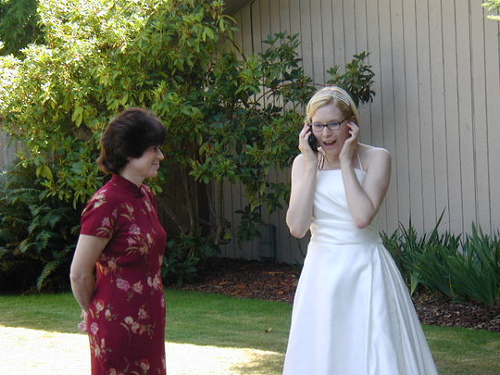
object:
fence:
[162, 4, 498, 261]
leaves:
[241, 264, 263, 280]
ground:
[0, 257, 500, 375]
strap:
[350, 146, 367, 172]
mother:
[69, 111, 170, 374]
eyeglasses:
[309, 117, 350, 133]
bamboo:
[219, 49, 237, 272]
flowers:
[122, 229, 142, 250]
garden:
[409, 228, 499, 299]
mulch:
[213, 258, 285, 297]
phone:
[301, 112, 322, 152]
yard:
[0, 0, 500, 375]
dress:
[279, 168, 440, 375]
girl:
[277, 84, 440, 375]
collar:
[111, 176, 145, 195]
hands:
[74, 308, 93, 333]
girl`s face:
[306, 100, 353, 154]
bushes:
[1, 157, 99, 312]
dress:
[77, 173, 171, 375]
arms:
[68, 200, 116, 309]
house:
[114, 0, 500, 285]